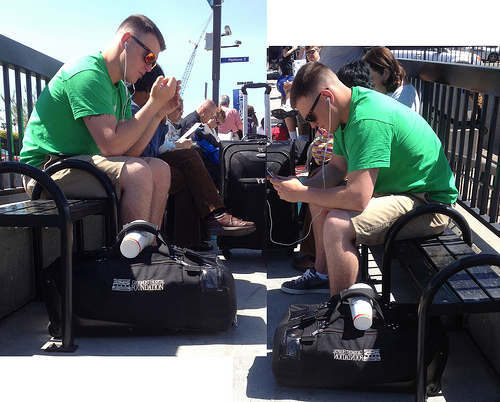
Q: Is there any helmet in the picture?
A: No, there are no helmets.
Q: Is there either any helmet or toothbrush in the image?
A: No, there are no helmets or toothbrushes.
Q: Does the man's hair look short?
A: Yes, the hair is short.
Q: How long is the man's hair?
A: The hair is short.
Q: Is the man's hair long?
A: No, the hair is short.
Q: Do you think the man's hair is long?
A: No, the hair is short.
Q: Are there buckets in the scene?
A: No, there are no buckets.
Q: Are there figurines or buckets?
A: No, there are no buckets or figurines.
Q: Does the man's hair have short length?
A: Yes, the hair is short.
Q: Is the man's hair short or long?
A: The hair is short.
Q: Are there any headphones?
A: Yes, there are headphones.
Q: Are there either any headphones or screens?
A: Yes, there are headphones.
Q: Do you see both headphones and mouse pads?
A: No, there are headphones but no mouse pads.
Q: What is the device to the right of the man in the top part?
A: The device is headphones.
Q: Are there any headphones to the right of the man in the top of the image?
A: Yes, there are headphones to the right of the man.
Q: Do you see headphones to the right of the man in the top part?
A: Yes, there are headphones to the right of the man.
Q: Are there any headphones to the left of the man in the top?
A: No, the headphones are to the right of the man.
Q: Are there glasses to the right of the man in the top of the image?
A: No, there are headphones to the right of the man.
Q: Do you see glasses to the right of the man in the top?
A: No, there are headphones to the right of the man.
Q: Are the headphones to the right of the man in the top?
A: Yes, the headphones are to the right of the man.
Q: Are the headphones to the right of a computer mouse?
A: No, the headphones are to the right of the man.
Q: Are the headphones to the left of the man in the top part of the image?
A: No, the headphones are to the right of the man.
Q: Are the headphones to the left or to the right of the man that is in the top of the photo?
A: The headphones are to the right of the man.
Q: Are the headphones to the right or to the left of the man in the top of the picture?
A: The headphones are to the right of the man.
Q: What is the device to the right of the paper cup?
A: The device is headphones.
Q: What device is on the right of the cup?
A: The device is headphones.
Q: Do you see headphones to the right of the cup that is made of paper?
A: Yes, there are headphones to the right of the cup.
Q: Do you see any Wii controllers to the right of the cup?
A: No, there are headphones to the right of the cup.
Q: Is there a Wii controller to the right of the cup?
A: No, there are headphones to the right of the cup.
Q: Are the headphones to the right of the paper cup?
A: Yes, the headphones are to the right of the cup.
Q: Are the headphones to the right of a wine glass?
A: No, the headphones are to the right of the cup.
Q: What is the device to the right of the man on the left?
A: The device is headphones.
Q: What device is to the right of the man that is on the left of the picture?
A: The device is headphones.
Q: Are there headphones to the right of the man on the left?
A: Yes, there are headphones to the right of the man.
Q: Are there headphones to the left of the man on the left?
A: No, the headphones are to the right of the man.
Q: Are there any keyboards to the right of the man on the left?
A: No, there are headphones to the right of the man.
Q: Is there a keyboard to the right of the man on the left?
A: No, there are headphones to the right of the man.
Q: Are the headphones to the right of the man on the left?
A: Yes, the headphones are to the right of the man.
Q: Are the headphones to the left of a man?
A: No, the headphones are to the right of a man.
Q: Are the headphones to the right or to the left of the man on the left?
A: The headphones are to the right of the man.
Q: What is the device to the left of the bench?
A: The device is headphones.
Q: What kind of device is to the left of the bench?
A: The device is headphones.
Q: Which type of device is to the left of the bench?
A: The device is headphones.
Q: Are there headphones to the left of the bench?
A: Yes, there are headphones to the left of the bench.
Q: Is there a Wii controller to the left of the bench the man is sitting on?
A: No, there are headphones to the left of the bench.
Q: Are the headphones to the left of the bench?
A: Yes, the headphones are to the left of the bench.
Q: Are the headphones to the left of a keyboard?
A: No, the headphones are to the left of the bench.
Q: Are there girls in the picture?
A: No, there are no girls.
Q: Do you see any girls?
A: No, there are no girls.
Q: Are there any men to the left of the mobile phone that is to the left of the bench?
A: Yes, there is a man to the left of the cellphone.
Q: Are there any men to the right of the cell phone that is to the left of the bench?
A: No, the man is to the left of the mobile phone.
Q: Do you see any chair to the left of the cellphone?
A: No, there is a man to the left of the cellphone.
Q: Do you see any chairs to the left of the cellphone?
A: No, there is a man to the left of the cellphone.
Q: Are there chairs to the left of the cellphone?
A: No, there is a man to the left of the cellphone.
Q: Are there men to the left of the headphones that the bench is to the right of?
A: Yes, there is a man to the left of the headphones.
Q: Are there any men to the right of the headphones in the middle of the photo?
A: No, the man is to the left of the headphones.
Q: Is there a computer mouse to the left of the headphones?
A: No, there is a man to the left of the headphones.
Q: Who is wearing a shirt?
A: The man is wearing a shirt.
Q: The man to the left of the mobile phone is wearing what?
A: The man is wearing a shirt.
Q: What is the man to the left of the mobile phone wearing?
A: The man is wearing a shirt.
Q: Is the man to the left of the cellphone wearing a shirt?
A: Yes, the man is wearing a shirt.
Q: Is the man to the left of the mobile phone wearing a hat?
A: No, the man is wearing a shirt.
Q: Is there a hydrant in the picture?
A: No, there are no fire hydrants.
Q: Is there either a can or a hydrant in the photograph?
A: No, there are no fire hydrants or cans.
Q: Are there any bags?
A: Yes, there is a bag.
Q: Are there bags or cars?
A: Yes, there is a bag.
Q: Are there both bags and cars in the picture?
A: No, there is a bag but no cars.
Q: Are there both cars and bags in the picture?
A: No, there is a bag but no cars.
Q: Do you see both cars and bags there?
A: No, there is a bag but no cars.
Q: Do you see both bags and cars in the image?
A: No, there is a bag but no cars.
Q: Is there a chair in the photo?
A: No, there are no chairs.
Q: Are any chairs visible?
A: No, there are no chairs.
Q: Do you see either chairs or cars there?
A: No, there are no chairs or cars.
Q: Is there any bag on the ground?
A: Yes, there is a bag on the ground.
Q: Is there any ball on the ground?
A: No, there is a bag on the ground.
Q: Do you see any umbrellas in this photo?
A: No, there are no umbrellas.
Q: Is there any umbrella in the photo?
A: No, there are no umbrellas.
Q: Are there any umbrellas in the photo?
A: No, there are no umbrellas.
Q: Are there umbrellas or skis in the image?
A: No, there are no umbrellas or skis.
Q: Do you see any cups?
A: Yes, there is a cup.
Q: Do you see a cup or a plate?
A: Yes, there is a cup.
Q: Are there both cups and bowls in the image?
A: No, there is a cup but no bowls.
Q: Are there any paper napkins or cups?
A: Yes, there is a paper cup.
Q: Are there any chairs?
A: No, there are no chairs.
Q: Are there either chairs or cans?
A: No, there are no chairs or cans.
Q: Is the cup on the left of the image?
A: Yes, the cup is on the left of the image.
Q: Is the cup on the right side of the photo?
A: No, the cup is on the left of the image.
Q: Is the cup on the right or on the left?
A: The cup is on the left of the image.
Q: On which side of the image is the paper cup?
A: The cup is on the left of the image.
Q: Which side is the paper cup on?
A: The cup is on the left of the image.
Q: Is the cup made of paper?
A: Yes, the cup is made of paper.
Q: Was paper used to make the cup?
A: Yes, the cup is made of paper.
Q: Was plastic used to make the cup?
A: No, the cup is made of paper.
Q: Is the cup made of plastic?
A: No, the cup is made of paper.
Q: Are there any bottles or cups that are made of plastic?
A: No, there is a cup but it is made of paper.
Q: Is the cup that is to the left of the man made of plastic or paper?
A: The cup is made of paper.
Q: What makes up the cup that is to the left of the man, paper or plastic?
A: The cup is made of paper.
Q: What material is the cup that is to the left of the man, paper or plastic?
A: The cup is made of paper.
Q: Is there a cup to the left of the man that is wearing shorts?
A: Yes, there is a cup to the left of the man.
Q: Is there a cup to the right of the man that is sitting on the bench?
A: No, the cup is to the left of the man.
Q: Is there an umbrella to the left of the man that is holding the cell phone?
A: No, there is a cup to the left of the man.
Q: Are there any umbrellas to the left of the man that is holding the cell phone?
A: No, there is a cup to the left of the man.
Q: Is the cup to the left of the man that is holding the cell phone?
A: Yes, the cup is to the left of the man.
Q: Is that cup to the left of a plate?
A: No, the cup is to the left of the man.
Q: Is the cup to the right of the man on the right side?
A: No, the cup is to the left of the man.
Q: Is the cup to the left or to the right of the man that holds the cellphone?
A: The cup is to the left of the man.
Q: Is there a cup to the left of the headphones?
A: Yes, there is a cup to the left of the headphones.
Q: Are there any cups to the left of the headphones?
A: Yes, there is a cup to the left of the headphones.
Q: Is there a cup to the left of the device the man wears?
A: Yes, there is a cup to the left of the headphones.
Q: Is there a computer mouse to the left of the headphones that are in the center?
A: No, there is a cup to the left of the headphones.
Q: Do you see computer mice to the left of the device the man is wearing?
A: No, there is a cup to the left of the headphones.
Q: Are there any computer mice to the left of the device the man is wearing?
A: No, there is a cup to the left of the headphones.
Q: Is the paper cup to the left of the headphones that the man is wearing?
A: Yes, the cup is to the left of the headphones.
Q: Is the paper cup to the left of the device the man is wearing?
A: Yes, the cup is to the left of the headphones.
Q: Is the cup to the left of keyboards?
A: No, the cup is to the left of the headphones.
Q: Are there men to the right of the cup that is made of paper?
A: Yes, there is a man to the right of the cup.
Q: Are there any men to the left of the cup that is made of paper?
A: No, the man is to the right of the cup.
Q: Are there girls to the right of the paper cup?
A: No, there is a man to the right of the cup.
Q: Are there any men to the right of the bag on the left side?
A: Yes, there is a man to the right of the bag.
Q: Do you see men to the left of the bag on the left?
A: No, the man is to the right of the bag.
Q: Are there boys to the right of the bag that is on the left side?
A: No, there is a man to the right of the bag.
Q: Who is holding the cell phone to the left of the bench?
A: The man is holding the mobile phone.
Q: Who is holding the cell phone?
A: The man is holding the mobile phone.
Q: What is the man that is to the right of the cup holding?
A: The man is holding the cellphone.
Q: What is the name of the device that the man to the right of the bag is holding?
A: The device is a cell phone.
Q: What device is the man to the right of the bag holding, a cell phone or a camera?
A: The man is holding a cell phone.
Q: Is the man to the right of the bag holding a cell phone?
A: Yes, the man is holding a cell phone.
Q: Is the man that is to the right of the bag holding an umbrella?
A: No, the man is holding a cell phone.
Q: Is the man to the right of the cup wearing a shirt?
A: Yes, the man is wearing a shirt.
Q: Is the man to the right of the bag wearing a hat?
A: No, the man is wearing a shirt.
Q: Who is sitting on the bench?
A: The man is sitting on the bench.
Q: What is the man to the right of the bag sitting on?
A: The man is sitting on the bench.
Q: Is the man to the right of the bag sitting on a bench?
A: Yes, the man is sitting on a bench.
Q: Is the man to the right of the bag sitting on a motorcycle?
A: No, the man is sitting on a bench.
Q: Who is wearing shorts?
A: The man is wearing shorts.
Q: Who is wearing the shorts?
A: The man is wearing shorts.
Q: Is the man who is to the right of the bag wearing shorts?
A: Yes, the man is wearing shorts.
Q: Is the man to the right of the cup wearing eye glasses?
A: No, the man is wearing shorts.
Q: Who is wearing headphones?
A: The man is wearing headphones.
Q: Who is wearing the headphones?
A: The man is wearing headphones.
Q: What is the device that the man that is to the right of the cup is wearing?
A: The device is headphones.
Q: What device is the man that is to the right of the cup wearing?
A: The man is wearing headphones.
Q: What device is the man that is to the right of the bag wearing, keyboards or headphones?
A: The man is wearing headphones.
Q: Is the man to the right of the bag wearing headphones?
A: Yes, the man is wearing headphones.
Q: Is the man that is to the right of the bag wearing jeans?
A: No, the man is wearing headphones.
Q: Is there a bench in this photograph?
A: Yes, there is a bench.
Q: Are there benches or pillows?
A: Yes, there is a bench.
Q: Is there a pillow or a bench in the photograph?
A: Yes, there is a bench.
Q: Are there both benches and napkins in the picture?
A: No, there is a bench but no napkins.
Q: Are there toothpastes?
A: No, there are no toothpastes.